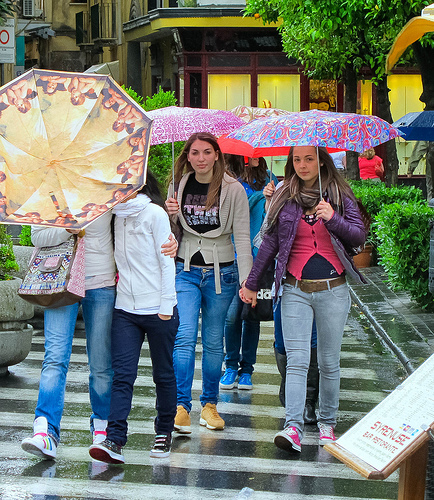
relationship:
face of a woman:
[183, 137, 228, 180] [155, 127, 233, 358]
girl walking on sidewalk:
[239, 146, 369, 452] [29, 452, 377, 479]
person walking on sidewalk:
[167, 132, 253, 433] [29, 452, 377, 479]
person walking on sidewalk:
[88, 191, 182, 466] [29, 452, 377, 479]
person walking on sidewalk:
[19, 210, 179, 457] [29, 452, 377, 479]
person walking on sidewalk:
[221, 153, 267, 389] [29, 452, 377, 479]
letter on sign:
[0, 29, 8, 45] [1, 17, 18, 63]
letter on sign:
[400, 435, 411, 445] [333, 344, 418, 481]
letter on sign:
[393, 429, 405, 445] [327, 355, 432, 479]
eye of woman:
[188, 145, 200, 158] [255, 140, 378, 450]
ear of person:
[212, 149, 219, 160] [161, 130, 256, 435]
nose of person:
[199, 151, 205, 162] [161, 130, 256, 435]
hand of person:
[162, 194, 183, 218] [161, 130, 256, 435]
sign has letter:
[324, 352, 433, 498] [400, 434, 413, 444]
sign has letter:
[324, 352, 433, 498] [371, 417, 383, 426]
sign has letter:
[324, 352, 433, 498] [379, 424, 387, 435]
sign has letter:
[324, 352, 433, 498] [382, 424, 391, 438]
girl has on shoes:
[239, 146, 369, 452] [270, 416, 334, 461]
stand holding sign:
[313, 362, 431, 496] [318, 349, 428, 483]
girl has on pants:
[244, 146, 367, 450] [278, 275, 352, 429]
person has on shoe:
[161, 130, 256, 435] [172, 402, 194, 442]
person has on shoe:
[161, 130, 256, 435] [198, 399, 227, 432]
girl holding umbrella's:
[239, 146, 369, 452] [1, 90, 404, 233]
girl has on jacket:
[239, 146, 369, 452] [242, 174, 368, 309]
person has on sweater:
[103, 186, 176, 328] [107, 195, 168, 313]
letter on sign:
[398, 432, 413, 447] [343, 350, 431, 471]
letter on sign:
[393, 432, 406, 445] [359, 416, 407, 453]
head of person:
[158, 122, 242, 210] [216, 151, 278, 389]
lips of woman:
[193, 158, 210, 171] [159, 129, 244, 435]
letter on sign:
[398, 432, 413, 447] [339, 357, 432, 477]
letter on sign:
[381, 440, 389, 449] [331, 345, 433, 474]